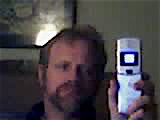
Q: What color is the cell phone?
A: Gray.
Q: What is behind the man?
A: A picture.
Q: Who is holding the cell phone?
A: A man.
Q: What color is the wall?
A: White.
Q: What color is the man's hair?
A: Brown.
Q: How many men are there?
A: One.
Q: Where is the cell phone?
A: In the man's hand.